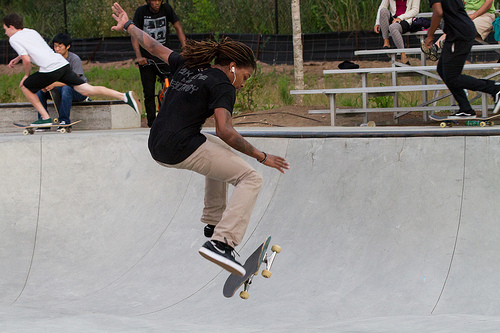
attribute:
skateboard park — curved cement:
[7, 121, 494, 333]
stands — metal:
[289, 5, 495, 121]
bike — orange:
[144, 56, 168, 105]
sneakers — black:
[193, 219, 249, 279]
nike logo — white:
[209, 237, 231, 255]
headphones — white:
[229, 63, 239, 84]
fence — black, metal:
[9, 1, 374, 60]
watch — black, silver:
[119, 18, 136, 35]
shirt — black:
[145, 49, 239, 166]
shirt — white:
[8, 27, 70, 77]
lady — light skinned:
[370, 1, 423, 71]